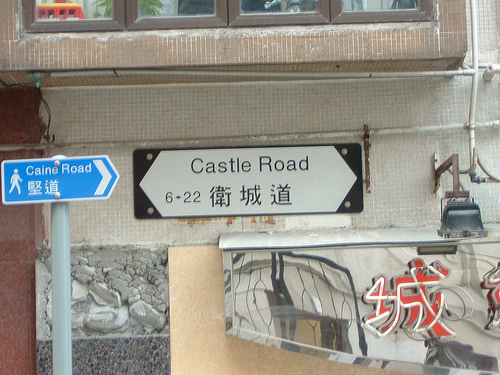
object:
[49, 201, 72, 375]
pole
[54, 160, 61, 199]
rivets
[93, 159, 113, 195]
arrow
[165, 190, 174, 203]
6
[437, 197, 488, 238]
headlight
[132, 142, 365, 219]
sign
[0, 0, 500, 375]
building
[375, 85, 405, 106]
tile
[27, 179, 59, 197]
writing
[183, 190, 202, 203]
22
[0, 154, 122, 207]
sign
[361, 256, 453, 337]
red sign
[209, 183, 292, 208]
characters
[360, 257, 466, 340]
chinese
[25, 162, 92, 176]
caine road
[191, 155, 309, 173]
castle road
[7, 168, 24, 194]
person